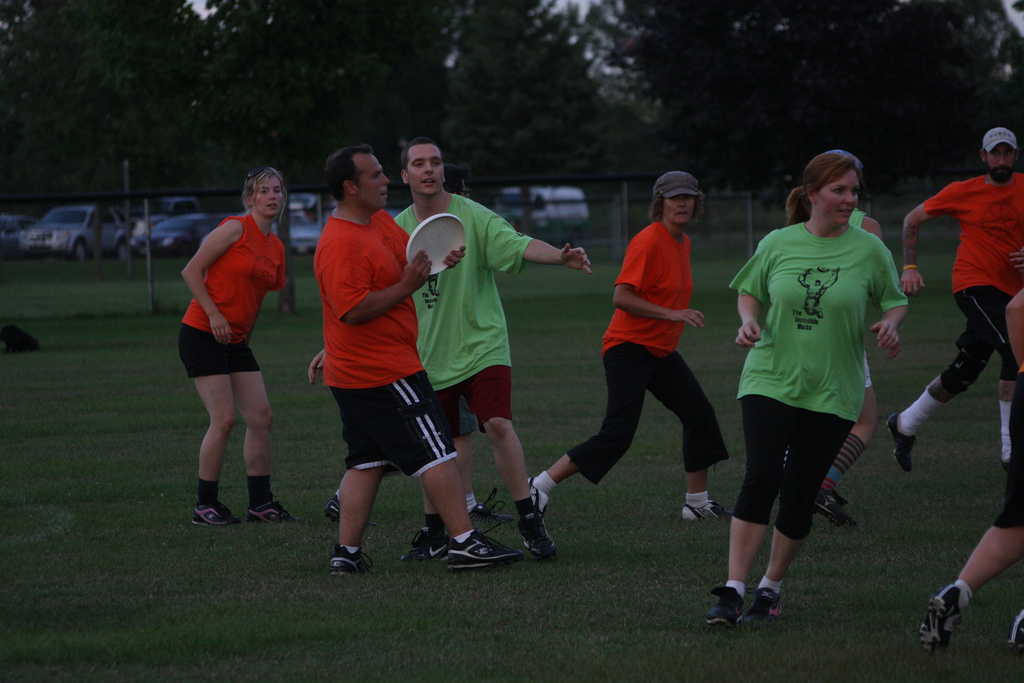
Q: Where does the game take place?
A: On a grassy field for sports.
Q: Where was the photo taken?
A: On a grassy field for outdoor activities.